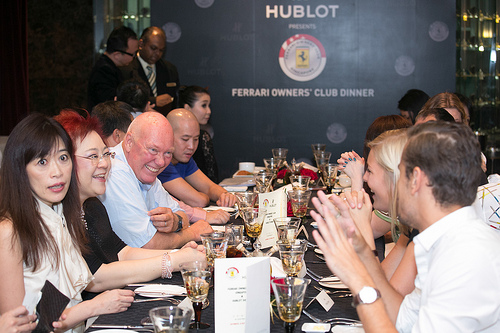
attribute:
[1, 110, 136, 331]
person — sitting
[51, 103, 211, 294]
person — sitting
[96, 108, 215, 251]
person — sitting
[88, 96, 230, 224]
person — sitting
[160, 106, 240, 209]
person — sitting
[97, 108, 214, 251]
man — smiling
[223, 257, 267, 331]
menu — white